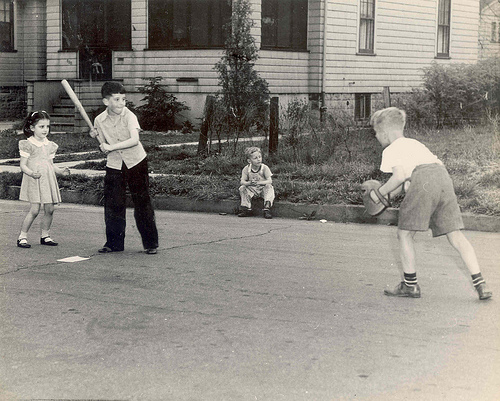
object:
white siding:
[117, 6, 320, 92]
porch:
[49, 42, 112, 123]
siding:
[233, 1, 262, 47]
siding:
[39, 54, 79, 79]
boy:
[358, 106, 495, 300]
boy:
[235, 146, 275, 218]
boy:
[88, 79, 160, 255]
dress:
[17, 136, 61, 203]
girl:
[16, 108, 60, 250]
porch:
[352, 88, 372, 121]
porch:
[251, 2, 312, 52]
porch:
[52, 2, 229, 51]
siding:
[113, 51, 308, 94]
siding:
[326, 68, 400, 96]